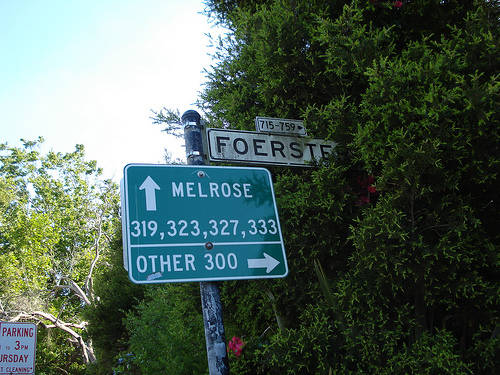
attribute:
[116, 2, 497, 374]
trees — standing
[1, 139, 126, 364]
tree — standing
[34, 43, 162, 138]
cloud — part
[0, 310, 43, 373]
sign letters — red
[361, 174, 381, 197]
objects — pink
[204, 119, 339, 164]
street sign — white, black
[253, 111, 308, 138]
sign — white, black, street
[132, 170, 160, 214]
arrow — white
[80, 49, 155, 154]
clouds — white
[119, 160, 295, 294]
sign — large, green, street, white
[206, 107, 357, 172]
sign — White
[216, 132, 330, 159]
letters — black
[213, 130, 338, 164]
letters — white 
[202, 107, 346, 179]
sign — white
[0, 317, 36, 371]
parking sign — red , white 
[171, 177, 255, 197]
letters — white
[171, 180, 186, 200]
letters — white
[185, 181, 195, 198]
letters — white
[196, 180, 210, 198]
letters — white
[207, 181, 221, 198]
letters — white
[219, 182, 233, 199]
letters — white